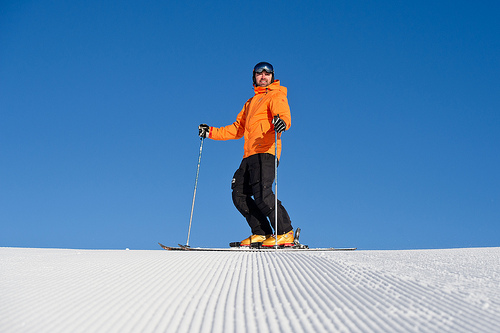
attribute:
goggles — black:
[249, 63, 295, 77]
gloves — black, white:
[195, 119, 212, 138]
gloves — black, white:
[269, 112, 289, 134]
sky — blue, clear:
[1, 0, 495, 245]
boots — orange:
[217, 217, 289, 251]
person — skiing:
[146, 36, 404, 294]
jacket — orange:
[173, 43, 314, 161]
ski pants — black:
[231, 152, 293, 234]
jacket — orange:
[204, 75, 298, 160]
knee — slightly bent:
[231, 174, 248, 205]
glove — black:
[270, 112, 286, 134]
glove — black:
[194, 121, 211, 139]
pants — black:
[212, 137, 325, 264]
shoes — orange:
[239, 228, 294, 245]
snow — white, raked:
[0, 246, 498, 331]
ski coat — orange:
[208, 80, 293, 157]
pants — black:
[232, 153, 298, 230]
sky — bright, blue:
[322, 36, 479, 185]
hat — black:
[249, 57, 279, 84]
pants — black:
[225, 152, 295, 238]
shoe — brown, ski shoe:
[260, 227, 295, 249]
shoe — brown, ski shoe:
[235, 234, 271, 248]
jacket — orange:
[205, 78, 292, 164]